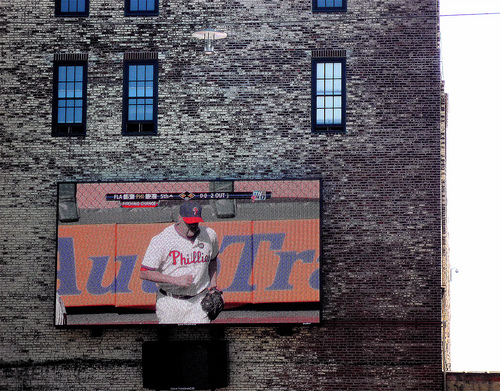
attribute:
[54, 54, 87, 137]
window — blue, black framed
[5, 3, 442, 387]
building — black brick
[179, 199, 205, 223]
hat — blue 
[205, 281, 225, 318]
glove — black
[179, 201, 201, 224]
cap — red 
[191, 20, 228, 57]
light — hanging, on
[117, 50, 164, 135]
window — glass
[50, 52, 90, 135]
window — glass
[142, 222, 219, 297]
shirt — white 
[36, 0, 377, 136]
windows — blue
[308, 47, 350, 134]
window — Black 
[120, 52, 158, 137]
window — Black 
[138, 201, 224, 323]
player — phillies, baseball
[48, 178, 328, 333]
screen — television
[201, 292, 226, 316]
glove — black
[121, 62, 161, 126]
windows — blue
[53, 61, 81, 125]
windows — blue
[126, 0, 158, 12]
windows — blue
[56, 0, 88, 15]
windows — blue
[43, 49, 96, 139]
window — Black 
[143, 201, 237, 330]
player — baseball